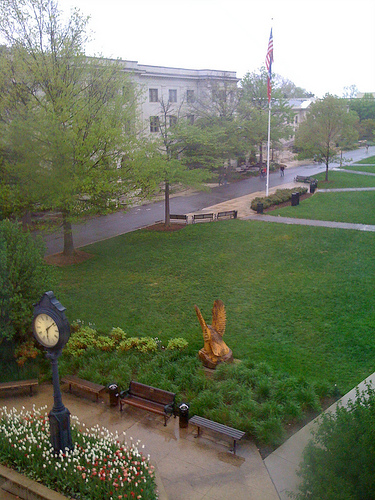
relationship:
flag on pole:
[266, 24, 275, 106] [267, 111, 271, 196]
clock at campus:
[28, 292, 75, 454] [0, 0, 375, 499]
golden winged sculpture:
[211, 342, 225, 356] [196, 302, 237, 370]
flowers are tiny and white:
[92, 433, 125, 461] [86, 444, 96, 467]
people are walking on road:
[278, 163, 286, 177] [195, 194, 217, 205]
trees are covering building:
[20, 77, 99, 243] [138, 71, 194, 123]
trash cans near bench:
[178, 404, 190, 433] [119, 382, 177, 425]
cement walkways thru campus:
[196, 464, 274, 494] [0, 0, 375, 499]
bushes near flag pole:
[272, 194, 291, 203] [267, 111, 271, 196]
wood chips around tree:
[60, 257, 69, 268] [158, 155, 177, 232]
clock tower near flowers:
[28, 292, 75, 454] [92, 433, 125, 461]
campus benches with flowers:
[0, 0, 375, 499] [92, 433, 125, 461]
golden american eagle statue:
[211, 342, 225, 356] [196, 302, 237, 370]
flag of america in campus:
[266, 24, 275, 106] [0, 0, 375, 499]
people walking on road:
[278, 163, 286, 177] [195, 194, 217, 205]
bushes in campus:
[272, 194, 291, 203] [0, 0, 375, 499]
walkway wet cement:
[307, 217, 346, 229] [196, 464, 274, 494]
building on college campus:
[138, 71, 194, 123] [15, 7, 374, 287]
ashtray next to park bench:
[110, 384, 118, 390] [119, 382, 177, 425]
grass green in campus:
[319, 259, 361, 306] [0, 0, 375, 499]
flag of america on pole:
[266, 24, 275, 106] [267, 111, 271, 196]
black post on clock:
[52, 367, 62, 404] [28, 292, 75, 454]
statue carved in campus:
[196, 302, 237, 370] [0, 0, 375, 499]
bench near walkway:
[119, 382, 177, 425] [307, 217, 346, 229]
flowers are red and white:
[92, 433, 125, 461] [86, 444, 96, 467]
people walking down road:
[278, 163, 286, 177] [195, 194, 217, 205]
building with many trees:
[138, 71, 194, 123] [20, 77, 99, 243]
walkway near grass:
[307, 217, 346, 229] [319, 259, 361, 306]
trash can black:
[178, 404, 190, 433] [52, 367, 62, 404]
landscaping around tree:
[5, 347, 32, 373] [158, 155, 177, 232]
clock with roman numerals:
[28, 292, 75, 454] [41, 321, 57, 342]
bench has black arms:
[119, 382, 177, 425] [166, 400, 176, 416]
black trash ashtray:
[52, 367, 62, 404] [109, 383, 118, 403]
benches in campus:
[89, 380, 247, 438] [0, 0, 375, 499]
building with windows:
[138, 71, 194, 123] [149, 91, 176, 131]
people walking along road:
[278, 163, 286, 177] [195, 194, 217, 205]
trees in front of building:
[20, 77, 99, 243] [138, 71, 194, 123]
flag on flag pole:
[266, 24, 275, 106] [267, 111, 271, 196]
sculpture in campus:
[196, 302, 237, 370] [0, 0, 375, 499]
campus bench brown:
[0, 0, 375, 499] [134, 402, 154, 408]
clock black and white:
[28, 292, 75, 454] [42, 321, 46, 331]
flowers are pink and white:
[92, 433, 125, 461] [86, 444, 96, 467]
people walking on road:
[278, 163, 286, 177] [46, 141, 375, 258]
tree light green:
[158, 155, 177, 232] [87, 103, 109, 137]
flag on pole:
[266, 24, 275, 106] [264, 40, 274, 201]